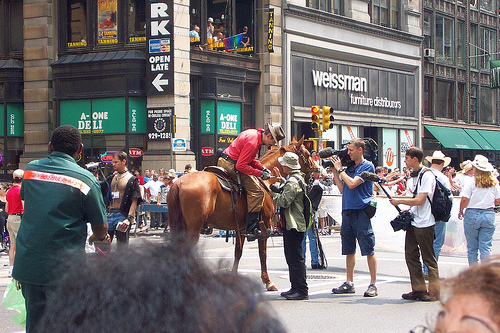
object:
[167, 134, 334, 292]
horse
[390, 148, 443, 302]
guy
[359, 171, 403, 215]
mic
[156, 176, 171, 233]
people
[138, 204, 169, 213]
barricade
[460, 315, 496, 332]
eyebrows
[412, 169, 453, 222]
backpack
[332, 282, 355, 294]
shoe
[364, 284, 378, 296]
shoe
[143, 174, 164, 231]
man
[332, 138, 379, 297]
guy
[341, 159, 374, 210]
shirt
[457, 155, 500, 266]
woman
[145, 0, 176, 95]
sign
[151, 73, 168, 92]
arrow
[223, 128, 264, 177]
man shirt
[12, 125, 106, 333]
guy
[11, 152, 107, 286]
shirt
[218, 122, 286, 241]
guy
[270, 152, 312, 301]
guy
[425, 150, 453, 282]
man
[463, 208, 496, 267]
jeans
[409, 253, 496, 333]
woman